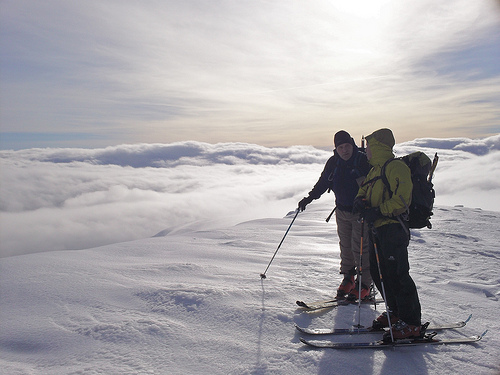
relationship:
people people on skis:
[298, 127, 439, 342] [292, 293, 322, 340]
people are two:
[298, 127, 439, 342] [306, 164, 401, 350]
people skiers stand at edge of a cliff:
[298, 127, 439, 342] [1, 318, 396, 354]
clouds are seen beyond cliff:
[30, 70, 265, 193] [5, 165, 200, 308]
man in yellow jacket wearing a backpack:
[354, 128, 439, 341] [324, 130, 436, 210]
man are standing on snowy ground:
[354, 128, 439, 341] [44, 354, 207, 375]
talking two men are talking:
[301, 124, 438, 332] [301, 108, 440, 209]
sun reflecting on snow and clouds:
[247, 100, 340, 148] [38, 70, 304, 131]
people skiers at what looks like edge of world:
[298, 127, 439, 342] [60, 170, 460, 330]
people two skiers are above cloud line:
[298, 127, 439, 342] [14, 214, 284, 375]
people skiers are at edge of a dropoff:
[298, 127, 439, 342] [1, 142, 274, 375]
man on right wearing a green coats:
[297, 131, 373, 300] [306, 150, 365, 211]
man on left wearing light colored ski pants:
[354, 128, 439, 341] [373, 244, 422, 344]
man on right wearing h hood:
[354, 128, 439, 341] [362, 155, 405, 245]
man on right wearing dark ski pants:
[354, 128, 439, 341] [366, 269, 419, 375]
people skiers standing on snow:
[298, 127, 439, 342] [322, 188, 412, 326]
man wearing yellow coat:
[354, 128, 439, 341] [356, 157, 409, 224]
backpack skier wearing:
[421, 151, 432, 229] [372, 135, 434, 304]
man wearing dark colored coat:
[297, 131, 373, 300] [324, 128, 354, 268]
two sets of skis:
[297, 172, 419, 364] [297, 108, 426, 344]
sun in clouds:
[288, 8, 399, 59] [78, 19, 487, 136]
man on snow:
[297, 131, 373, 300] [40, 186, 386, 363]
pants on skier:
[366, 237, 469, 349] [342, 133, 453, 326]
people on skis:
[298, 127, 439, 342] [315, 298, 498, 370]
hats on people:
[321, 128, 374, 152] [317, 120, 467, 285]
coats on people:
[310, 140, 440, 221] [317, 120, 467, 285]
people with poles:
[315, 114, 455, 288] [265, 196, 315, 272]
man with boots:
[297, 131, 373, 300] [319, 265, 379, 295]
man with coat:
[354, 128, 439, 341] [355, 148, 419, 216]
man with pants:
[354, 128, 439, 341] [353, 232, 434, 313]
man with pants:
[330, 137, 458, 340] [380, 250, 461, 334]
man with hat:
[303, 115, 402, 311] [320, 131, 382, 177]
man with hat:
[297, 131, 373, 300] [368, 123, 426, 144]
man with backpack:
[354, 128, 439, 341] [403, 151, 432, 228]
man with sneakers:
[297, 131, 373, 300] [308, 260, 385, 310]